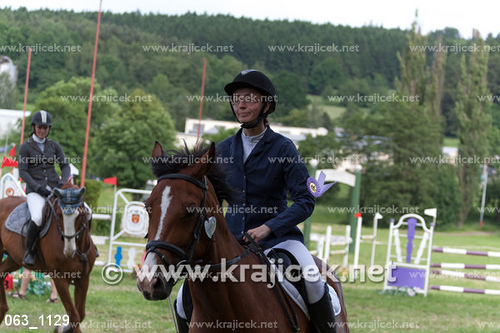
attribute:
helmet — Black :
[225, 70, 275, 123]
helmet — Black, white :
[31, 108, 53, 126]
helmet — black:
[221, 69, 273, 103]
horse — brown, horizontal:
[137, 140, 348, 332]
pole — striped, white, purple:
[431, 245, 498, 259]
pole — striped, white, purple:
[430, 261, 498, 269]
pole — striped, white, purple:
[430, 269, 497, 283]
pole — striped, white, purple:
[428, 284, 498, 296]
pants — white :
[25, 191, 46, 226]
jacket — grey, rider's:
[17, 134, 69, 194]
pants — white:
[229, 210, 346, 315]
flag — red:
[90, 161, 147, 201]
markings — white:
[143, 180, 183, 281]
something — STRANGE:
[143, 168, 215, 258]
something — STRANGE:
[52, 186, 84, 244]